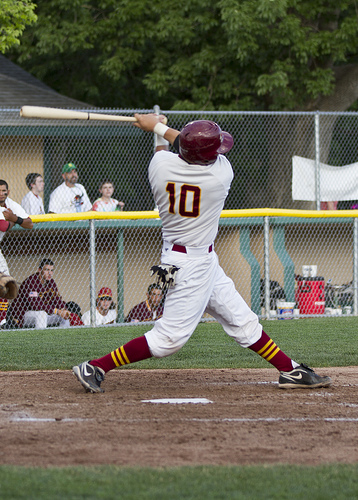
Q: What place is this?
A: It is a field.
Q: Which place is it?
A: It is a field.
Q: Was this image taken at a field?
A: Yes, it was taken in a field.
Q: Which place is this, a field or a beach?
A: It is a field.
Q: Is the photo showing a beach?
A: No, the picture is showing a field.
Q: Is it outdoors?
A: Yes, it is outdoors.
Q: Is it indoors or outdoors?
A: It is outdoors.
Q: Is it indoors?
A: No, it is outdoors.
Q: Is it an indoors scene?
A: No, it is outdoors.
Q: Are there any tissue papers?
A: No, there are no tissue papers.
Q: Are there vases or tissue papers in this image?
A: No, there are no tissue papers or vases.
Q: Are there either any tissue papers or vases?
A: No, there are no tissue papers or vases.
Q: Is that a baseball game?
A: Yes, that is a baseball game.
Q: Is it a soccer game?
A: No, that is a baseball game.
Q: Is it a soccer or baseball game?
A: That is a baseball game.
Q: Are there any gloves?
A: Yes, there are gloves.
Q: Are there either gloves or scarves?
A: Yes, there are gloves.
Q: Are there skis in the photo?
A: No, there are no skis.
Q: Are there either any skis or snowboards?
A: No, there are no skis or snowboards.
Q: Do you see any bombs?
A: No, there are no bombs.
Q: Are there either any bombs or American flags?
A: No, there are no bombs or American flags.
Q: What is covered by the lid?
A: The cooler is covered by the lid.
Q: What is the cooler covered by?
A: The cooler is covered by the lid.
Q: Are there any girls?
A: No, there are no girls.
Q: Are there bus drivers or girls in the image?
A: No, there are no girls or bus drivers.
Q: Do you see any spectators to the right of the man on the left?
A: Yes, there are spectators to the right of the man.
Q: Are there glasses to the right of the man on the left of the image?
A: No, there are spectators to the right of the man.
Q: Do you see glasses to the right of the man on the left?
A: No, there are spectators to the right of the man.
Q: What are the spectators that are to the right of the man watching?
A: The spectators are watching the game.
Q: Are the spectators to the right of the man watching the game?
A: Yes, the spectators are watching the game.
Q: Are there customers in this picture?
A: No, there are no customers.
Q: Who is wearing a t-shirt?
A: The man is wearing a t-shirt.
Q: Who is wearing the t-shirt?
A: The man is wearing a t-shirt.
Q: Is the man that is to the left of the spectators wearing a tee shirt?
A: Yes, the man is wearing a tee shirt.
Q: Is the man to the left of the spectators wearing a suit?
A: No, the man is wearing a tee shirt.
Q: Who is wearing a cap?
A: The man is wearing a cap.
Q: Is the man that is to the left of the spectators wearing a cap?
A: Yes, the man is wearing a cap.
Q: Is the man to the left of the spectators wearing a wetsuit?
A: No, the man is wearing a cap.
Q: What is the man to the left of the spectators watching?
A: The man is watching the game.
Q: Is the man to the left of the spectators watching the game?
A: Yes, the man is watching the game.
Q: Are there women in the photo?
A: No, there are no women.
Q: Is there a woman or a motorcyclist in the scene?
A: No, there are no women or bikers.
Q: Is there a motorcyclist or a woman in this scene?
A: No, there are no women or bikers.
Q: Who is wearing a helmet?
A: The man is wearing a helmet.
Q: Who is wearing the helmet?
A: The man is wearing a helmet.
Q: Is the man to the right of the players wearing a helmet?
A: Yes, the man is wearing a helmet.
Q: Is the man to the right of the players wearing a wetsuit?
A: No, the man is wearing a helmet.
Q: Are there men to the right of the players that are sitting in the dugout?
A: Yes, there is a man to the right of the players.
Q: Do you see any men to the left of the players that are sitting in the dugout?
A: No, the man is to the right of the players.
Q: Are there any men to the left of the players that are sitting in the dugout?
A: No, the man is to the right of the players.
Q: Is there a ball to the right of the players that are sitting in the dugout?
A: No, there is a man to the right of the players.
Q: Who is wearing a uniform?
A: The man is wearing a uniform.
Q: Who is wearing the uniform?
A: The man is wearing a uniform.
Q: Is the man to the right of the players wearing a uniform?
A: Yes, the man is wearing a uniform.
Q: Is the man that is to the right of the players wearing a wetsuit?
A: No, the man is wearing a uniform.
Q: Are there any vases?
A: No, there are no vases.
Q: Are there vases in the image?
A: No, there are no vases.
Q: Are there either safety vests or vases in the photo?
A: No, there are no vases or safety vests.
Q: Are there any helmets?
A: Yes, there is a helmet.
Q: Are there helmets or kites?
A: Yes, there is a helmet.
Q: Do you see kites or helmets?
A: Yes, there is a helmet.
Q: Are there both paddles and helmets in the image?
A: No, there is a helmet but no paddles.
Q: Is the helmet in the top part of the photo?
A: Yes, the helmet is in the top of the image.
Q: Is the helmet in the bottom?
A: No, the helmet is in the top of the image.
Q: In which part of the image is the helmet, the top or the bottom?
A: The helmet is in the top of the image.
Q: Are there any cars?
A: No, there are no cars.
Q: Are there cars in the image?
A: No, there are no cars.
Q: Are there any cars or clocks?
A: No, there are no cars or clocks.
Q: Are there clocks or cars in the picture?
A: No, there are no cars or clocks.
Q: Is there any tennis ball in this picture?
A: No, there are no tennis balls.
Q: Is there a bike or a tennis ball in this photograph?
A: No, there are no tennis balls or bikes.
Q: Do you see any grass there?
A: Yes, there is grass.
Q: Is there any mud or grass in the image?
A: Yes, there is grass.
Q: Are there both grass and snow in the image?
A: No, there is grass but no snow.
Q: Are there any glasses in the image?
A: No, there are no glasses.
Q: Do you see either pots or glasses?
A: No, there are no glasses or pots.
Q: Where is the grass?
A: The grass is on the field.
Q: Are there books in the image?
A: No, there are no books.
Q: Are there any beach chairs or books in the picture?
A: No, there are no books or beach chairs.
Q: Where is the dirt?
A: The dirt is on the field.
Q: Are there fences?
A: Yes, there is a fence.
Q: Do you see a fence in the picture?
A: Yes, there is a fence.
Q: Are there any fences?
A: Yes, there is a fence.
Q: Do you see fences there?
A: Yes, there is a fence.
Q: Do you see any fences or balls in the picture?
A: Yes, there is a fence.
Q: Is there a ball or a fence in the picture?
A: Yes, there is a fence.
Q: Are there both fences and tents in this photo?
A: No, there is a fence but no tents.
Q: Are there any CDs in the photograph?
A: No, there are no cds.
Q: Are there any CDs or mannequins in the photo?
A: No, there are no CDs or mannequins.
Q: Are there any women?
A: No, there are no women.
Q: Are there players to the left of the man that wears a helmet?
A: Yes, there are players to the left of the man.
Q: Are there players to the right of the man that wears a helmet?
A: No, the players are to the left of the man.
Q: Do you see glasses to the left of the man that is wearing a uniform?
A: No, there are players to the left of the man.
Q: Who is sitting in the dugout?
A: The players are sitting in the dugout.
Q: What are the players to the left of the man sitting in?
A: The players are sitting in the dugout.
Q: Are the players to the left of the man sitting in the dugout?
A: Yes, the players are sitting in the dugout.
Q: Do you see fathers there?
A: No, there are no fathers.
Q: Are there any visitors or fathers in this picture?
A: No, there are no fathers or visitors.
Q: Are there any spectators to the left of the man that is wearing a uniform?
A: Yes, there are spectators to the left of the man.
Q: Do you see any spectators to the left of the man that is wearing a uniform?
A: Yes, there are spectators to the left of the man.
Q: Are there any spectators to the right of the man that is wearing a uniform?
A: No, the spectators are to the left of the man.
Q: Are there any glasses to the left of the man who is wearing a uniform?
A: No, there are spectators to the left of the man.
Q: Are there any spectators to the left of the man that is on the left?
A: Yes, there are spectators to the left of the man.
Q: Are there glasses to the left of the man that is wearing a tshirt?
A: No, there are spectators to the left of the man.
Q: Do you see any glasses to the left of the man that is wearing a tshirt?
A: No, there are spectators to the left of the man.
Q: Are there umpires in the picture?
A: No, there are no umpires.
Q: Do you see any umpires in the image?
A: No, there are no umpires.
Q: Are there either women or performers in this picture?
A: No, there are no women or performers.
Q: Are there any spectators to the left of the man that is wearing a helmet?
A: Yes, there are spectators to the left of the man.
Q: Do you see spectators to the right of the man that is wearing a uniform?
A: No, the spectators are to the left of the man.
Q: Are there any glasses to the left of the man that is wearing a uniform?
A: No, there are spectators to the left of the man.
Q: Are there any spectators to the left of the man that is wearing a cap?
A: Yes, there are spectators to the left of the man.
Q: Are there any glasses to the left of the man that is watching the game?
A: No, there are spectators to the left of the man.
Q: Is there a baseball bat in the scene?
A: Yes, there is a baseball bat.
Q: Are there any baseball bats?
A: Yes, there is a baseball bat.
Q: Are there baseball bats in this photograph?
A: Yes, there is a baseball bat.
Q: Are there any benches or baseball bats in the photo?
A: Yes, there is a baseball bat.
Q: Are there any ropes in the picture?
A: No, there are no ropes.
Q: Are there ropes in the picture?
A: No, there are no ropes.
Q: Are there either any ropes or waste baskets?
A: No, there are no ropes or waste baskets.